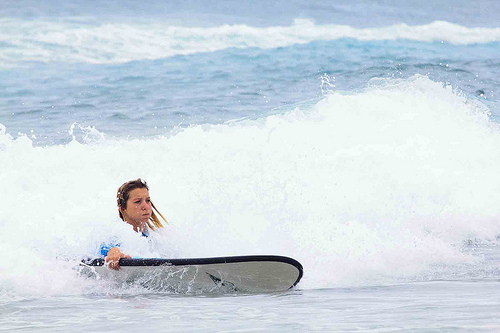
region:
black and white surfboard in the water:
[62, 254, 302, 296]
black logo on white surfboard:
[206, 272, 246, 298]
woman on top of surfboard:
[90, 178, 177, 269]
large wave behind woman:
[0, 72, 498, 293]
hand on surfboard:
[105, 249, 133, 270]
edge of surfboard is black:
[80, 254, 304, 293]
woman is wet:
[93, 178, 179, 270]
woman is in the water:
[97, 172, 177, 269]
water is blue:
[0, 0, 497, 331]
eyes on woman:
[133, 198, 141, 205]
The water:
[311, 201, 404, 310]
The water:
[334, 190, 386, 287]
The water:
[311, 228, 336, 274]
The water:
[371, 213, 386, 250]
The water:
[351, 222, 379, 294]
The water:
[353, 200, 391, 280]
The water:
[331, 207, 389, 319]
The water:
[351, 197, 398, 270]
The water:
[350, 219, 387, 308]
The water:
[359, 247, 389, 313]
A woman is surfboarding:
[68, 138, 309, 330]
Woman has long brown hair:
[96, 173, 186, 238]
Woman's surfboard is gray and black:
[76, 233, 342, 298]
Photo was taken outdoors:
[6, 3, 498, 331]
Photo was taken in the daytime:
[6, 7, 498, 327]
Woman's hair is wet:
[110, 166, 185, 235]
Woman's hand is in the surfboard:
[97, 237, 142, 284]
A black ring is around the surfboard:
[61, 238, 311, 305]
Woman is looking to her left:
[108, 162, 166, 244]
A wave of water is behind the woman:
[2, 117, 491, 278]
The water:
[387, 276, 389, 304]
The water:
[354, 191, 398, 281]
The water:
[371, 261, 411, 328]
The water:
[369, 254, 397, 310]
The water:
[349, 240, 379, 273]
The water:
[359, 223, 394, 291]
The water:
[360, 196, 431, 321]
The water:
[382, 240, 427, 325]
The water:
[330, 267, 373, 304]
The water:
[379, 261, 388, 331]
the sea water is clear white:
[347, 315, 356, 327]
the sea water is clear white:
[357, 303, 367, 321]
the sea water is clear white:
[344, 273, 366, 331]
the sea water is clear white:
[319, 314, 329, 331]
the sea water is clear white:
[355, 292, 373, 329]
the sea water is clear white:
[322, 316, 342, 329]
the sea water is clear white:
[333, 306, 343, 321]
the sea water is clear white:
[367, 303, 387, 330]